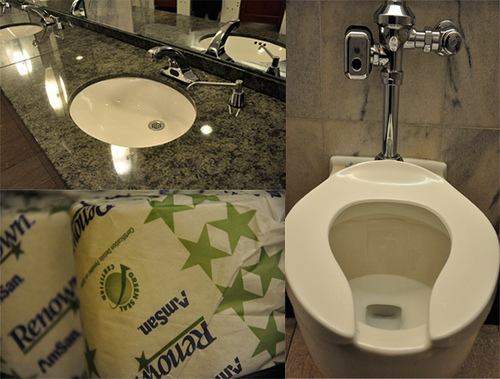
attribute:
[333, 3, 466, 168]
valve — chrome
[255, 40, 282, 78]
soap pump — chrome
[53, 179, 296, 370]
toilet paper — wrapped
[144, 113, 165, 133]
drain — chrome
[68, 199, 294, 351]
toilet paper — wrapped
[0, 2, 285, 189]
countertop — grey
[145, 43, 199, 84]
faucet — chrome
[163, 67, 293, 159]
pump — chrome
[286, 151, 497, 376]
toilet — white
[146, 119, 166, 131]
drain — metal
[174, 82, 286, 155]
countertop — marble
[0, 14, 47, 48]
sink — white, inset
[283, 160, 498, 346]
seat — white 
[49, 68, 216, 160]
sink — white, inset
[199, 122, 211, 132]
light — white 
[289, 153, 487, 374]
seat — white